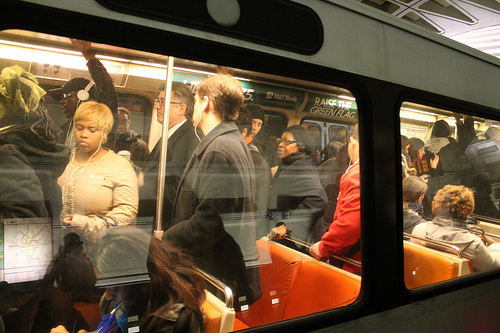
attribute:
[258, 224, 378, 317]
seat — colored orange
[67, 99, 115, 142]
hair — blonde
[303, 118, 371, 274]
person — orange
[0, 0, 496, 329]
vehicle — public transport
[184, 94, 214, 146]
headphones — white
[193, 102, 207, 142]
headphones — over-ear, white